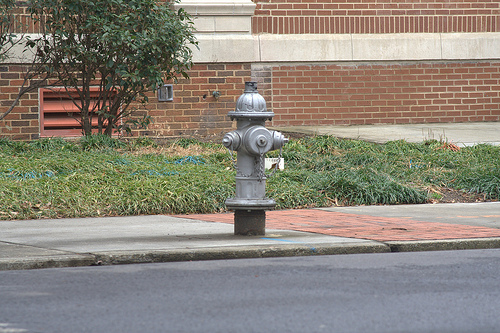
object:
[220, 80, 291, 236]
hydrant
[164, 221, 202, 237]
sidewalk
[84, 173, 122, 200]
grass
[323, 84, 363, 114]
wall